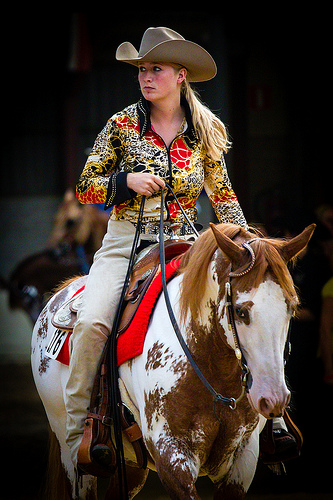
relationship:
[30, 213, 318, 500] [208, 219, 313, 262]
horse has ears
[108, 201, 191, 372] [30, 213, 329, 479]
thread attached to horse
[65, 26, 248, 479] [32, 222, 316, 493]
contestant riding horse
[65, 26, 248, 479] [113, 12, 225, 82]
contestant has hat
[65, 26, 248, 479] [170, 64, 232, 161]
contestant has hair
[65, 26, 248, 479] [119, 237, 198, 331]
contestant on brown saddle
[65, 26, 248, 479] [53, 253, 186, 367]
contestant on blanket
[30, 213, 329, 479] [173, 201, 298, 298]
horse has mane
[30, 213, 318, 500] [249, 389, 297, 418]
horse has nose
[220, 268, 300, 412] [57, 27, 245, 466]
face of girl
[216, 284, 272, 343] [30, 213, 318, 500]
eye of horse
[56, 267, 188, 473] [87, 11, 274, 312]
leg of girl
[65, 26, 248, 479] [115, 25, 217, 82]
contestant wearing hat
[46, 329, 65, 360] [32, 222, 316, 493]
176 on horse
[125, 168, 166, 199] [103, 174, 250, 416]
hand holding reins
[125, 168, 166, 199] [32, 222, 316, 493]
hand of horse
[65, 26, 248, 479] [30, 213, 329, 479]
contestant sitting horse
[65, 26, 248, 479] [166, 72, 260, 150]
contestant has hair